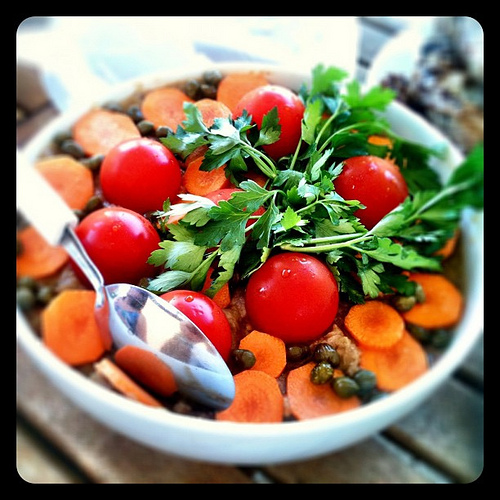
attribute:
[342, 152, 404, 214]
tomato — big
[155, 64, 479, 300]
parsley — green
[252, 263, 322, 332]
tomatoes — red 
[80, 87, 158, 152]
carrots — round, sliced, orange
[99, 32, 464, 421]
vegetable — green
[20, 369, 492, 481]
boards — brown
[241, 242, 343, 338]
tomato — big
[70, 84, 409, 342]
tomato — big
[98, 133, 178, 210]
tomato — big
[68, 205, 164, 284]
tomato — big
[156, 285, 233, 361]
tomato — big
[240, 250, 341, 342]
tomato — big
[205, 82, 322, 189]
tomato — big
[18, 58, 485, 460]
bowl — white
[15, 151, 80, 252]
handle — white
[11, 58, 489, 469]
white bowl — deep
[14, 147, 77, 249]
handle — white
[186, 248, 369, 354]
fruit — red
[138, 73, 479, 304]
vegetable — green, leafy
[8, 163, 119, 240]
handle — white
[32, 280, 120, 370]
carrot — chopped